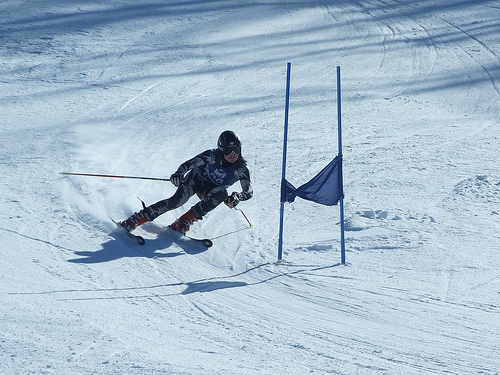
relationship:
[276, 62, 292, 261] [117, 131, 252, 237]
slalom pole near person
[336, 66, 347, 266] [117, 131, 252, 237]
slalom pole near person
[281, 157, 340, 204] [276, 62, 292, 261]
flag attached to slalom pole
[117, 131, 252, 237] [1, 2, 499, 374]
person kicks up snow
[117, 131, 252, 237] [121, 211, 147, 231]
person wearing boot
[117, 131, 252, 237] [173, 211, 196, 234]
person wearing boot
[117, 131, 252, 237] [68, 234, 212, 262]
person casting shadow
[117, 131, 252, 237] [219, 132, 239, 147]
person wearing helmet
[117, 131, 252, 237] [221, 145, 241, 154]
person wearing goggles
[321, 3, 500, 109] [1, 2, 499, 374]
tracks on top of snow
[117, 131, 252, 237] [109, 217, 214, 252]
person wearing skis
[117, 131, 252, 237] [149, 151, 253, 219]
person wearing suit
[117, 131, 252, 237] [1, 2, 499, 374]
person skiing on snow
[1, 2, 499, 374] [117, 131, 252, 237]
snow under person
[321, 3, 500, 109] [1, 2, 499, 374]
tracks on surface of snow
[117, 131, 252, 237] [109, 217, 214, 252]
person riding on skis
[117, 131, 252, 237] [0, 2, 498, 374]
person skiing down slope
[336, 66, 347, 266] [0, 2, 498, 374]
slalom pole located on slope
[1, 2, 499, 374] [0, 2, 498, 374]
snow on surface of slope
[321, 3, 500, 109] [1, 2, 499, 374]
tracks visible in snow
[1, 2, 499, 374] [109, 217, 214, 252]
snow kicked up from skis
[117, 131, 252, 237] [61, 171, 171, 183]
person holding ski pole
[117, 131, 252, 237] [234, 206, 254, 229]
person holding ski pole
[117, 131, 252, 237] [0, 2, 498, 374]
person skiing on slope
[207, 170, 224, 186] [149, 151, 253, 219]
writing printed on suit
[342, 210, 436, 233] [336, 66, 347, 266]
snow pile next to slalom pole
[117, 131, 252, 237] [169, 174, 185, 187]
person wearing glove